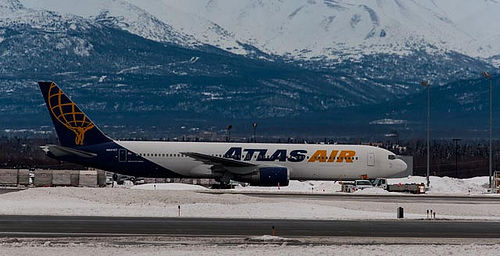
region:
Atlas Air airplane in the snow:
[38, 80, 407, 185]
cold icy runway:
[1, 213, 498, 237]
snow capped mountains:
[1, 0, 498, 85]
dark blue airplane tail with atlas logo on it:
[36, 80, 111, 142]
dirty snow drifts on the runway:
[1, 187, 498, 218]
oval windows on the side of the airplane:
[138, 151, 182, 158]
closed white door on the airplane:
[366, 150, 376, 165]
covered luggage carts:
[0, 168, 105, 185]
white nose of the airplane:
[388, 158, 407, 175]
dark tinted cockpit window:
[385, 152, 397, 161]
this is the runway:
[152, 213, 227, 230]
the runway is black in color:
[221, 215, 253, 234]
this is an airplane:
[26, 80, 416, 192]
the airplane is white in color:
[153, 144, 165, 150]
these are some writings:
[227, 145, 357, 165]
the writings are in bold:
[228, 146, 356, 163]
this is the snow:
[293, 193, 323, 222]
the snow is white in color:
[253, 196, 293, 210]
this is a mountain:
[218, 7, 483, 105]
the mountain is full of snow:
[263, 3, 336, 50]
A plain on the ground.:
[38, 81, 409, 191]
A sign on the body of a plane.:
[226, 146, 351, 163]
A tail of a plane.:
[34, 76, 109, 164]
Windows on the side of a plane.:
[140, 149, 362, 161]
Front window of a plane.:
[387, 152, 397, 160]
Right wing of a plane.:
[182, 148, 261, 180]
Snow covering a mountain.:
[1, 0, 494, 63]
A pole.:
[484, 65, 494, 192]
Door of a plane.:
[367, 154, 374, 169]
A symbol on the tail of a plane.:
[46, 82, 95, 147]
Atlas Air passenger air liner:
[32, 78, 417, 195]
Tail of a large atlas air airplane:
[33, 76, 125, 173]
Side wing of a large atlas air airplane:
[180, 148, 258, 178]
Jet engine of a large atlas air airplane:
[211, 166, 258, 183]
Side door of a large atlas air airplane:
[365, 150, 375, 169]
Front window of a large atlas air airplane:
[387, 152, 399, 161]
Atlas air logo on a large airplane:
[43, 83, 110, 148]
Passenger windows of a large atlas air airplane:
[135, 150, 187, 159]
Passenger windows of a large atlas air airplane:
[225, 153, 364, 164]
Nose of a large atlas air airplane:
[401, 159, 408, 172]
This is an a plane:
[22, 70, 417, 190]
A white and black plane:
[31, 68, 430, 200]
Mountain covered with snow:
[21, 18, 107, 68]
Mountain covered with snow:
[101, 8, 186, 105]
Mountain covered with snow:
[201, 31, 262, 136]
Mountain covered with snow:
[285, 30, 360, 140]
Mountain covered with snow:
[335, 15, 443, 53]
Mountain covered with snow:
[198, 0, 328, 65]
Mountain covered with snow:
[434, 2, 496, 58]